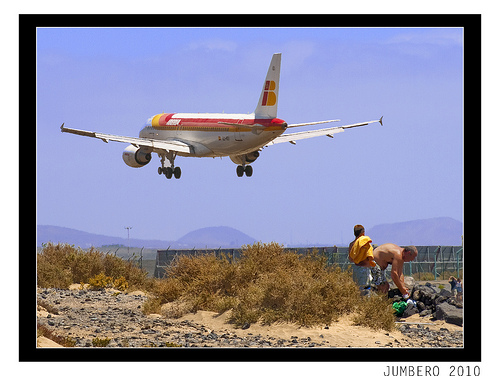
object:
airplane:
[61, 54, 384, 178]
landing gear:
[157, 165, 182, 182]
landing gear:
[235, 165, 253, 178]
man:
[349, 223, 373, 296]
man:
[371, 240, 418, 299]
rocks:
[384, 282, 463, 329]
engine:
[121, 142, 152, 168]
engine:
[229, 151, 261, 165]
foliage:
[38, 241, 397, 332]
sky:
[35, 27, 461, 247]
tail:
[256, 53, 281, 119]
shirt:
[348, 236, 374, 264]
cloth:
[391, 296, 405, 312]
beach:
[35, 269, 465, 349]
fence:
[154, 243, 464, 283]